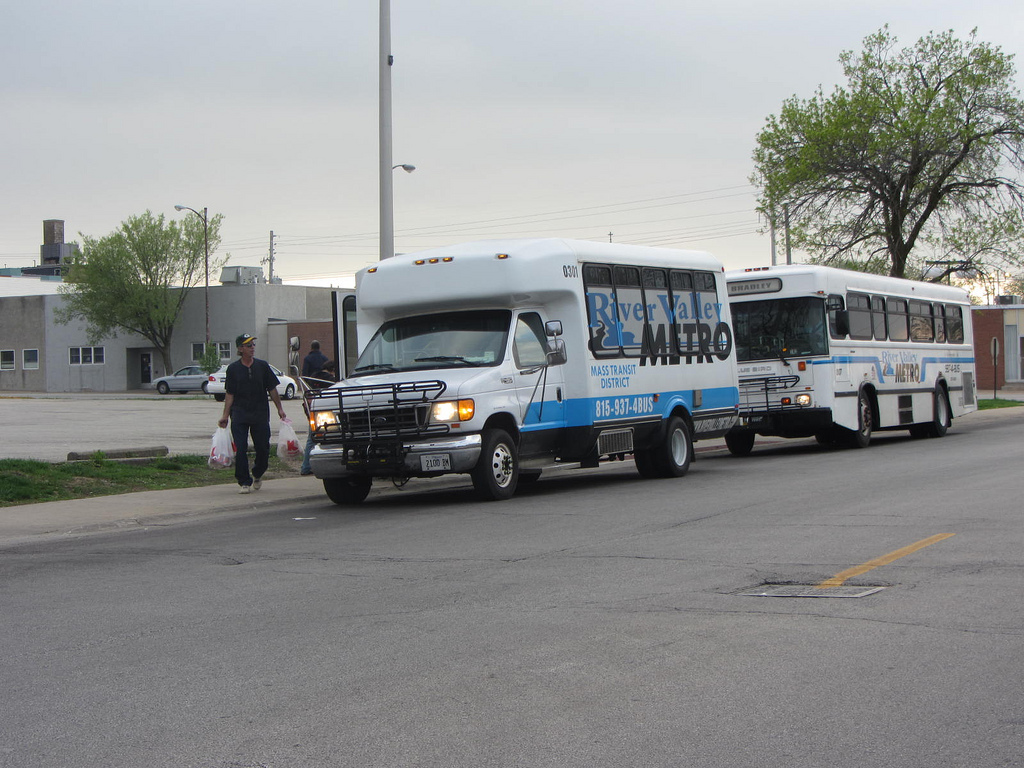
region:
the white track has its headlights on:
[310, 402, 473, 421]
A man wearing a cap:
[197, 310, 295, 415]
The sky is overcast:
[455, 46, 694, 217]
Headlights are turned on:
[296, 376, 500, 498]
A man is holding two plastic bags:
[195, 296, 314, 527]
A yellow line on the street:
[799, 514, 976, 631]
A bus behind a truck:
[600, 221, 997, 484]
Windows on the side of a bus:
[825, 276, 1000, 363]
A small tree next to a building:
[72, 199, 221, 397]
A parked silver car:
[133, 343, 220, 420]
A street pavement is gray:
[328, 559, 718, 752]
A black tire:
[631, 397, 714, 497]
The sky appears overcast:
[485, 41, 728, 216]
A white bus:
[747, 254, 1004, 466]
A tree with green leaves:
[764, 20, 984, 287]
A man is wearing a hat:
[208, 291, 282, 396]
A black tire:
[442, 431, 551, 516]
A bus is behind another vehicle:
[288, 197, 994, 602]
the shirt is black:
[225, 356, 280, 421]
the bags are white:
[197, 416, 314, 484]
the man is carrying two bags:
[198, 321, 315, 500]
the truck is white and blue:
[353, 258, 777, 503]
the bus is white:
[739, 261, 1000, 505]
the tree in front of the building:
[46, 215, 203, 390]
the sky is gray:
[129, 147, 301, 221]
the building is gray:
[37, 297, 237, 381]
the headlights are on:
[312, 403, 513, 449]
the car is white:
[273, 360, 311, 399]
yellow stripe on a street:
[828, 529, 968, 581]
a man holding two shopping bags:
[212, 330, 302, 490]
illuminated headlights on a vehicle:
[315, 399, 487, 442]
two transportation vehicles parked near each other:
[325, 242, 994, 498]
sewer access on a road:
[733, 570, 885, 606]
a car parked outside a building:
[142, 358, 212, 393]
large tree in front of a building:
[70, 201, 211, 367]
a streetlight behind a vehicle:
[369, 2, 415, 256]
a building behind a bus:
[970, 288, 1022, 409]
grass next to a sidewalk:
[5, 459, 202, 501]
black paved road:
[119, 544, 964, 734]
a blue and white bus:
[296, 236, 739, 506]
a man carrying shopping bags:
[189, 317, 311, 523]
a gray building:
[8, 279, 208, 406]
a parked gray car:
[144, 358, 215, 406]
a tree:
[62, 203, 224, 384]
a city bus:
[713, 266, 992, 451]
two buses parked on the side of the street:
[300, 238, 991, 494]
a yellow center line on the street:
[789, 510, 983, 638]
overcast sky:
[433, 13, 738, 181]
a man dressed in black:
[222, 331, 286, 490]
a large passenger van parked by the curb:
[299, 232, 740, 495]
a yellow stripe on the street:
[817, 522, 972, 592]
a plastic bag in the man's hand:
[207, 424, 242, 464]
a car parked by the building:
[154, 363, 216, 395]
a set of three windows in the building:
[71, 344, 117, 364]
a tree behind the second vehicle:
[753, 39, 1022, 258]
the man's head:
[233, 332, 268, 362]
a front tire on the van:
[473, 420, 531, 501]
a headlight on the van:
[434, 402, 457, 423]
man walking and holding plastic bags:
[204, 327, 307, 496]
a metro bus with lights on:
[287, 235, 744, 507]